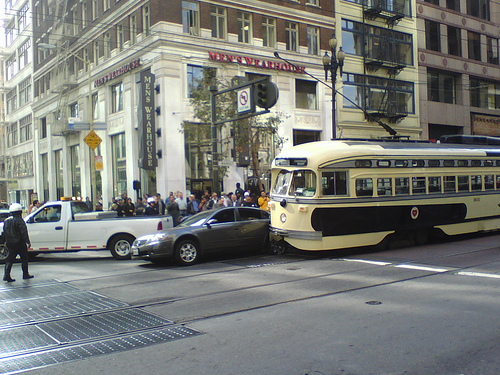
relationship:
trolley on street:
[271, 138, 496, 253] [2, 235, 500, 374]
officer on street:
[3, 203, 37, 285] [2, 235, 500, 374]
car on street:
[134, 204, 293, 265] [2, 235, 500, 374]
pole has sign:
[209, 76, 278, 196] [236, 83, 252, 115]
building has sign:
[0, 0, 499, 212] [141, 65, 161, 174]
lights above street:
[252, 82, 273, 111] [2, 235, 500, 374]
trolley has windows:
[271, 138, 496, 253] [356, 169, 497, 196]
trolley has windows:
[271, 138, 496, 253] [272, 167, 319, 199]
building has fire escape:
[0, 0, 499, 212] [47, 2, 91, 143]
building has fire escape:
[337, 2, 421, 141] [360, 2, 410, 121]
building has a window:
[0, 0, 499, 212] [292, 72, 323, 113]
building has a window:
[337, 2, 421, 141] [344, 73, 417, 114]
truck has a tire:
[4, 201, 174, 263] [111, 234, 134, 259]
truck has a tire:
[4, 201, 174, 263] [0, 236, 11, 265]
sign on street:
[236, 83, 252, 115] [2, 235, 500, 374]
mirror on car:
[209, 218, 215, 226] [134, 204, 293, 265]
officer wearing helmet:
[3, 203, 37, 285] [7, 203, 23, 214]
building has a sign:
[0, 0, 499, 212] [141, 65, 161, 174]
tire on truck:
[111, 234, 134, 259] [4, 201, 174, 263]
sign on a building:
[208, 47, 307, 77] [0, 0, 499, 212]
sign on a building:
[92, 59, 142, 88] [0, 0, 499, 212]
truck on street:
[4, 201, 174, 263] [2, 235, 500, 374]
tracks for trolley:
[2, 235, 500, 374] [271, 138, 496, 253]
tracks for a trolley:
[2, 228, 498, 365] [271, 138, 496, 253]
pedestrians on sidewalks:
[27, 186, 272, 228] [35, 216, 250, 244]